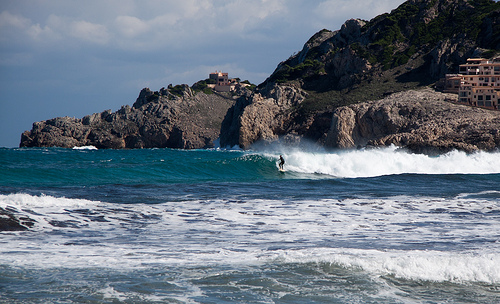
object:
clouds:
[0, 0, 401, 70]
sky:
[1, 0, 404, 150]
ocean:
[0, 147, 498, 301]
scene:
[0, 0, 497, 304]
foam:
[0, 190, 497, 304]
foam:
[209, 143, 499, 179]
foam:
[73, 145, 99, 150]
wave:
[0, 135, 500, 182]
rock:
[0, 143, 499, 304]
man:
[277, 155, 284, 171]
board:
[279, 168, 285, 172]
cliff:
[21, 0, 494, 157]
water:
[0, 145, 495, 304]